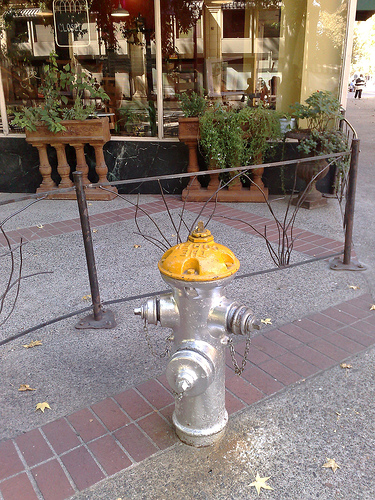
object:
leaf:
[21, 338, 43, 349]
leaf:
[17, 384, 37, 392]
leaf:
[34, 401, 51, 413]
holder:
[24, 117, 118, 200]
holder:
[178, 113, 276, 202]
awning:
[356, 0, 375, 21]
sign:
[52, 0, 91, 48]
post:
[343, 138, 360, 264]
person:
[354, 74, 366, 100]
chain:
[229, 343, 250, 376]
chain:
[145, 331, 168, 359]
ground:
[0, 80, 375, 500]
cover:
[158, 221, 241, 282]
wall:
[0, 0, 357, 194]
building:
[0, 0, 375, 195]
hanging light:
[111, 1, 130, 17]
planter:
[287, 90, 350, 193]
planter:
[172, 84, 284, 186]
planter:
[11, 50, 111, 135]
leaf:
[247, 471, 275, 497]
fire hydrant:
[134, 220, 263, 448]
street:
[0, 0, 375, 500]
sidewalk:
[0, 80, 375, 500]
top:
[157, 221, 241, 281]